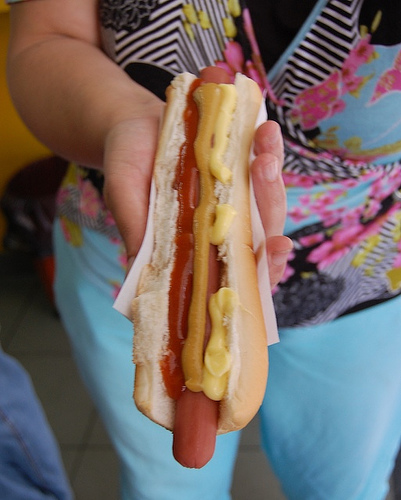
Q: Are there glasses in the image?
A: No, there are no glasses.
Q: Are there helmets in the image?
A: No, there are no helmets.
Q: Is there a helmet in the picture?
A: No, there are no helmets.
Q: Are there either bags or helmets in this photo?
A: No, there are no helmets or bags.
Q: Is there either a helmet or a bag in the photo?
A: No, there are no helmets or bags.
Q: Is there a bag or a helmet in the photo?
A: No, there are no helmets or bags.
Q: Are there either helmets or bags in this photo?
A: No, there are no helmets or bags.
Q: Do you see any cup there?
A: No, there are no cups.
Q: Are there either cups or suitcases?
A: No, there are no cups or suitcases.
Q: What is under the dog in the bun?
A: The napkin is under the dog.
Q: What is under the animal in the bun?
A: The napkin is under the dog.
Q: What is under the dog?
A: The napkin is under the dog.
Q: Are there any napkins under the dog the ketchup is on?
A: Yes, there is a napkin under the dog.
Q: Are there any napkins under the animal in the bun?
A: Yes, there is a napkin under the dog.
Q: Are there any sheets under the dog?
A: No, there is a napkin under the dog.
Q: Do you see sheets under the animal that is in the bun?
A: No, there is a napkin under the dog.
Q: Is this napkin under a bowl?
A: No, the napkin is under the dog.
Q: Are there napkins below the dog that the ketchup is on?
A: Yes, there is a napkin below the dog.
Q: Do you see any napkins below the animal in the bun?
A: Yes, there is a napkin below the dog.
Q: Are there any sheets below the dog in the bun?
A: No, there is a napkin below the dog.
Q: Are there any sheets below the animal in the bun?
A: No, there is a napkin below the dog.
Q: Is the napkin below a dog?
A: Yes, the napkin is below a dog.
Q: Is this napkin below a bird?
A: No, the napkin is below a dog.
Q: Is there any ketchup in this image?
A: Yes, there is ketchup.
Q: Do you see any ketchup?
A: Yes, there is ketchup.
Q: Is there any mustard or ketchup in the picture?
A: Yes, there is ketchup.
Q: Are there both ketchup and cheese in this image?
A: Yes, there are both ketchup and cheese.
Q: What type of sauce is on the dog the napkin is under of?
A: The sauce is ketchup.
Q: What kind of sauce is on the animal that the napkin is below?
A: The sauce is ketchup.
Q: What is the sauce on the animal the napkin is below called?
A: The sauce is ketchup.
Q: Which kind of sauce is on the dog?
A: The sauce is ketchup.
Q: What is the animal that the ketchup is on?
A: The animal is a dog.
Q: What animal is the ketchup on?
A: The ketchup is on the dog.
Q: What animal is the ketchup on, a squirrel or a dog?
A: The ketchup is on a dog.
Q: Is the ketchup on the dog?
A: Yes, the ketchup is on the dog.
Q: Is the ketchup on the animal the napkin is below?
A: Yes, the ketchup is on the dog.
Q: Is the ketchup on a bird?
A: No, the ketchup is on the dog.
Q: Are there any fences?
A: No, there are no fences.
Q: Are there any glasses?
A: No, there are no glasses.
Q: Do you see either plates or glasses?
A: No, there are no glasses or plates.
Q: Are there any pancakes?
A: No, there are no pancakes.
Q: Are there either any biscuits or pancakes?
A: No, there are no pancakes or biscuits.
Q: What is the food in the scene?
A: The food is a bun.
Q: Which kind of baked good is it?
A: The food is a bun.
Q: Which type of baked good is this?
A: This is a bun.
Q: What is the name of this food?
A: This is a bun.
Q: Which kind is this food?
A: This is a bun.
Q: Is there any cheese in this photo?
A: Yes, there is cheese.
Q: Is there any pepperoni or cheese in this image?
A: Yes, there is cheese.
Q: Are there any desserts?
A: No, there are no desserts.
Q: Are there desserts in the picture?
A: No, there are no desserts.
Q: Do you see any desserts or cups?
A: No, there are no desserts or cups.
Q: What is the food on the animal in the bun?
A: The food is cheese.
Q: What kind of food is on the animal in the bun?
A: The food is cheese.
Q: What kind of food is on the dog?
A: The food is cheese.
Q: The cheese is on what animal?
A: The cheese is on the dog.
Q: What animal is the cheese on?
A: The cheese is on the dog.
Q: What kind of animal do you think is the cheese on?
A: The cheese is on the dog.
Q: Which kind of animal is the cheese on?
A: The cheese is on the dog.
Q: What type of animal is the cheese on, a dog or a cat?
A: The cheese is on a dog.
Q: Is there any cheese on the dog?
A: Yes, there is cheese on the dog.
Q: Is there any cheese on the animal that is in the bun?
A: Yes, there is cheese on the dog.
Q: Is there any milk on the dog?
A: No, there is cheese on the dog.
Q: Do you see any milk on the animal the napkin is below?
A: No, there is cheese on the dog.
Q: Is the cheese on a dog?
A: Yes, the cheese is on a dog.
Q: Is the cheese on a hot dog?
A: No, the cheese is on a dog.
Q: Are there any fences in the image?
A: No, there are no fences.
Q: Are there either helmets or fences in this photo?
A: No, there are no fences or helmets.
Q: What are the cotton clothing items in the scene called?
A: The clothing items are pants.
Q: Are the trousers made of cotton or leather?
A: The trousers are made of cotton.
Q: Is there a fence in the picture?
A: No, there are no fences.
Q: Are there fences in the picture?
A: No, there are no fences.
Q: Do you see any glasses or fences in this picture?
A: No, there are no fences or glasses.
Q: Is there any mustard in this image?
A: Yes, there is mustard.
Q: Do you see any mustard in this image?
A: Yes, there is mustard.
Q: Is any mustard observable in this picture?
A: Yes, there is mustard.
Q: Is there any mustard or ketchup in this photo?
A: Yes, there is mustard.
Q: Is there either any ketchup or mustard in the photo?
A: Yes, there is mustard.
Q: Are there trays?
A: No, there are no trays.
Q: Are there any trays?
A: No, there are no trays.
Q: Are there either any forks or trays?
A: No, there are no trays or forks.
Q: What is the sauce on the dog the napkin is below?
A: The sauce is mustard.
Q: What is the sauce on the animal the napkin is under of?
A: The sauce is mustard.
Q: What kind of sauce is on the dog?
A: The sauce is mustard.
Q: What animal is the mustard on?
A: The mustard is on the dog.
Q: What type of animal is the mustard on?
A: The mustard is on the dog.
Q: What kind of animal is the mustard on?
A: The mustard is on the dog.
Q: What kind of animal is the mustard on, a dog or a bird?
A: The mustard is on a dog.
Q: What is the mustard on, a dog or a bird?
A: The mustard is on a dog.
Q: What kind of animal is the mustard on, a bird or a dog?
A: The mustard is on a dog.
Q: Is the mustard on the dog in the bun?
A: Yes, the mustard is on the dog.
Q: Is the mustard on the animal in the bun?
A: Yes, the mustard is on the dog.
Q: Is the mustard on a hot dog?
A: No, the mustard is on the dog.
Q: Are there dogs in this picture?
A: Yes, there is a dog.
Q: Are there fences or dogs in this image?
A: Yes, there is a dog.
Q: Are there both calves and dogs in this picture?
A: No, there is a dog but no calves.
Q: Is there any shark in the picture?
A: No, there are no sharks.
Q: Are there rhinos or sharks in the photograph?
A: No, there are no sharks or rhinos.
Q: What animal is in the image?
A: The animal is a dog.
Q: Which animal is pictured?
A: The animal is a dog.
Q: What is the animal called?
A: The animal is a dog.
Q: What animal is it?
A: The animal is a dog.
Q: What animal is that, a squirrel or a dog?
A: That is a dog.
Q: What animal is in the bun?
A: The dog is in the bun.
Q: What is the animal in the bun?
A: The animal is a dog.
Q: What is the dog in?
A: The dog is in the bun.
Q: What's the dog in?
A: The dog is in the bun.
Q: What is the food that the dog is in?
A: The food is a bun.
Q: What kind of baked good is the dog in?
A: The dog is in the bun.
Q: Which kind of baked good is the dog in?
A: The dog is in the bun.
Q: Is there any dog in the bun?
A: Yes, there is a dog in the bun.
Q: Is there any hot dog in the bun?
A: No, there is a dog in the bun.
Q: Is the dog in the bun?
A: Yes, the dog is in the bun.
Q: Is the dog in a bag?
A: No, the dog is in the bun.